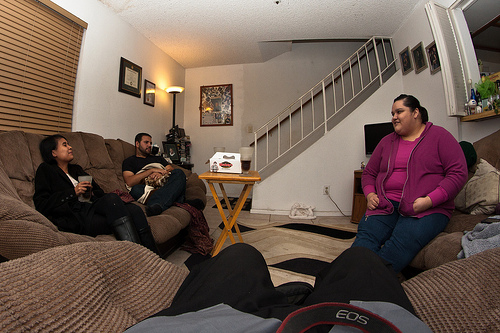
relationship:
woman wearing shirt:
[321, 64, 454, 279] [368, 120, 462, 205]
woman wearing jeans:
[321, 64, 454, 279] [343, 210, 440, 276]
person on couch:
[41, 133, 138, 233] [3, 132, 220, 237]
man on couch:
[120, 132, 187, 213] [3, 132, 220, 237]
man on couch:
[120, 124, 187, 207] [3, 132, 220, 237]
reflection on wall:
[145, 58, 170, 90] [89, 14, 233, 152]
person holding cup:
[41, 133, 138, 233] [78, 175, 94, 198]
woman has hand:
[321, 64, 454, 279] [410, 197, 461, 216]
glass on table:
[238, 144, 257, 171] [198, 155, 252, 227]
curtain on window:
[1, 14, 75, 106] [4, 2, 79, 133]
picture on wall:
[117, 56, 147, 100] [89, 14, 233, 152]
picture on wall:
[142, 78, 159, 111] [89, 14, 233, 152]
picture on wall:
[197, 81, 235, 128] [89, 14, 233, 152]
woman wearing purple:
[321, 64, 454, 279] [387, 133, 439, 193]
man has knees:
[120, 124, 187, 207] [170, 168, 192, 187]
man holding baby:
[120, 124, 187, 207] [144, 160, 175, 184]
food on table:
[206, 157, 238, 171] [198, 155, 252, 227]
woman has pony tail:
[321, 64, 454, 279] [409, 93, 437, 120]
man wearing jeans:
[120, 124, 187, 207] [137, 193, 183, 204]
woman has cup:
[41, 133, 138, 233] [74, 175, 88, 197]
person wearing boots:
[41, 133, 138, 233] [111, 211, 164, 246]